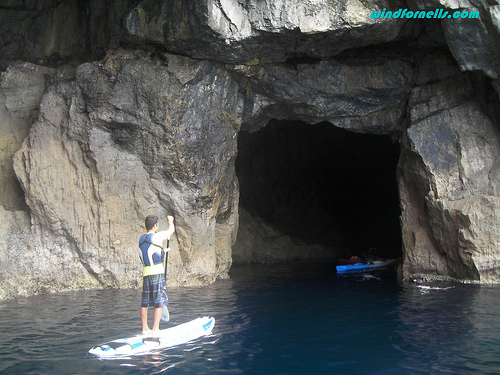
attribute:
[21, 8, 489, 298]
cave — open, large, beside rock, deep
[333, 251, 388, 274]
boat — in water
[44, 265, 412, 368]
water — blue, calm, beautiful, deep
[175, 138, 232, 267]
stone — rough, gray, black, brown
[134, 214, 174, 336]
person — paddling, light skinned, standing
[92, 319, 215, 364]
board — white, in water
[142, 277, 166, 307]
shorts — plaid blue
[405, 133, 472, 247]
rock — grey, large, huge, gigantic, old, gray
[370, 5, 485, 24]
writing — blue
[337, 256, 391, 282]
canoe — blue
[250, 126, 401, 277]
tunnel — dark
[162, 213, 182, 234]
arm — in air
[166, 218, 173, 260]
handle — black